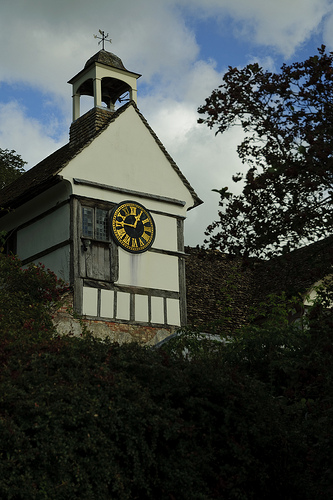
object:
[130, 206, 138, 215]
number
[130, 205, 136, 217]
grass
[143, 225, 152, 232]
grass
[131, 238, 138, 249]
grass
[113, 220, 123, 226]
grass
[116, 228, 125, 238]
grass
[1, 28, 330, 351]
building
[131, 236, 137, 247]
number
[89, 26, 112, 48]
vane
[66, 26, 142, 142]
cupola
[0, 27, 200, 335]
clock tower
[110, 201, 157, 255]
clock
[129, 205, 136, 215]
roman numeral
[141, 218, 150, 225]
roman numeral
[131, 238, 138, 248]
roman numeral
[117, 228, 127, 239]
roman numeral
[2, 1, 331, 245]
white clouds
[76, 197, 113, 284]
window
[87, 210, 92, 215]
pane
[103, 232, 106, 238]
pane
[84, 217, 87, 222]
pane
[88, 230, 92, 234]
pane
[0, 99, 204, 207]
roof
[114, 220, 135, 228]
hands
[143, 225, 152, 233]
roman numeral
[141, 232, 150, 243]
roman numeral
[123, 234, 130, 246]
roman numeral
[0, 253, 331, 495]
bushes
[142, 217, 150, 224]
numbers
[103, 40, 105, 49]
pole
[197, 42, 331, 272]
tree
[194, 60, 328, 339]
leaves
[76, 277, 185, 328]
wood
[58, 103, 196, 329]
wall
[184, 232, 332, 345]
wall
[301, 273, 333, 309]
archway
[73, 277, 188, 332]
frame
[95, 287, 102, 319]
slat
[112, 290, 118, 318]
slat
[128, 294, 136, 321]
slat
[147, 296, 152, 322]
slat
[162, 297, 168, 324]
slat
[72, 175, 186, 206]
slat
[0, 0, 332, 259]
sky